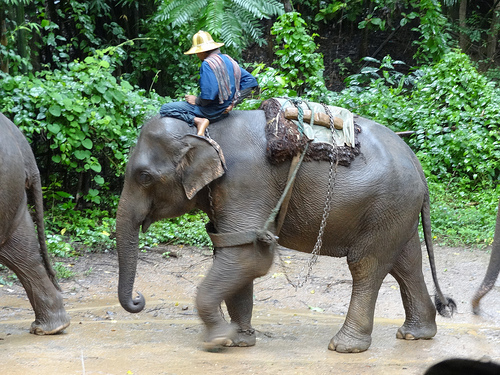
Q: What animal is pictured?
A: Elephants.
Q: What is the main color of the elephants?
A: Black.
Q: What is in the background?
A: Greenery.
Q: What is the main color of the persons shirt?
A: Blue.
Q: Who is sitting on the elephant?
A: Rider.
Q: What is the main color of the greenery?
A: Green.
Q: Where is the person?
A: On top of the elephant.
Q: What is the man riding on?
A: An elephant.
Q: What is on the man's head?
A: A hat.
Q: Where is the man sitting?
A: Near the elephant's head.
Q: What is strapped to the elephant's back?
A: A blanket.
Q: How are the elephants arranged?
A: In a line.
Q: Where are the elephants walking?
A: On a wet trail.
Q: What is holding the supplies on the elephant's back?
A: A chain.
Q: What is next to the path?
A: Bushes.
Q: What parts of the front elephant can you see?
A: The back leg and tail.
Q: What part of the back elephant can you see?
A: The trunk.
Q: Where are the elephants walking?
A: Through water.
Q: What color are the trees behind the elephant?
A: Green.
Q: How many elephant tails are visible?
A: Two.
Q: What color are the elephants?
A: Grey.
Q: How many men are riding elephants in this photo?
A: One.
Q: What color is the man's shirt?
A: Blue.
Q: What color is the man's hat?
A: Yellow.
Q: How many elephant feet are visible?
A: Five.